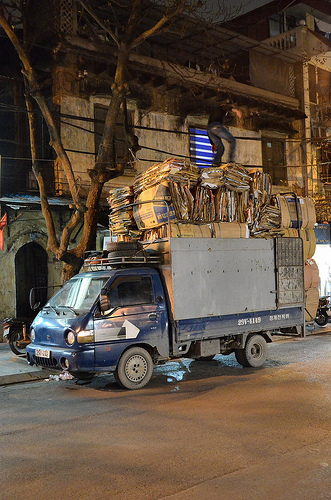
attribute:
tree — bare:
[2, 5, 243, 300]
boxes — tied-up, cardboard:
[100, 158, 320, 238]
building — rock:
[55, 6, 319, 192]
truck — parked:
[24, 190, 307, 390]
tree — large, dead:
[2, 0, 201, 280]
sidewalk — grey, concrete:
[1, 356, 25, 379]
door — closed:
[87, 261, 167, 394]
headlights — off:
[26, 325, 77, 349]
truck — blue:
[25, 227, 308, 394]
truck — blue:
[26, 236, 314, 389]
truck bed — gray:
[175, 274, 307, 319]